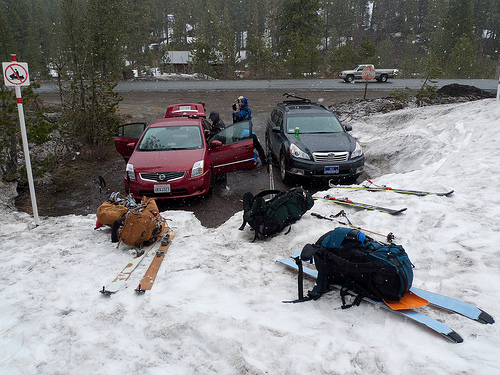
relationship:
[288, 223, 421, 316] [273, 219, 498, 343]
bag on top of skis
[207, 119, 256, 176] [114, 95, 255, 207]
door on vehicle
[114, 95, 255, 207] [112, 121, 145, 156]
vehicle has door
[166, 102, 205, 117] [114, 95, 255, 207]
trunk on car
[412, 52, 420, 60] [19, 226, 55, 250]
snow on ground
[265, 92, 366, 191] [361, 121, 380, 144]
vehicle by snow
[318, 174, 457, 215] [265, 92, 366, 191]
skis near car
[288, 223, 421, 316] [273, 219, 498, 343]
backpack on skis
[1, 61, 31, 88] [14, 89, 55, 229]
sign on pole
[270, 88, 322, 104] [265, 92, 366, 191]
rack on car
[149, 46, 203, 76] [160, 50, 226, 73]
cabin in picture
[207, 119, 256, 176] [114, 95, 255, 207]
door on car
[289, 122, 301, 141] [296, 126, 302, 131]
bottle has top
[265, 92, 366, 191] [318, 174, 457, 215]
car near ski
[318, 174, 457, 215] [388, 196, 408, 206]
ski on snow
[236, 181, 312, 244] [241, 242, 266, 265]
backpack on snow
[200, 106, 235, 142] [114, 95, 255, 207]
people in car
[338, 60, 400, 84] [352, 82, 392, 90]
car on road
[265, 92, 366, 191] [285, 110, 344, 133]
car has windshield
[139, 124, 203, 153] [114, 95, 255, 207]
windshield on car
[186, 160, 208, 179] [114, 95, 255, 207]
headlight on car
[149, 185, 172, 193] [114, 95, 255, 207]
plate on car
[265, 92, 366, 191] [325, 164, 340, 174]
car has plate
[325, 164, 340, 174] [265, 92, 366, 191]
plate on car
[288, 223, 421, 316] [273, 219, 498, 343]
bag on skis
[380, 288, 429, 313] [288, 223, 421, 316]
shovel under bag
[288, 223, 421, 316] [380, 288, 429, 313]
bag on shovel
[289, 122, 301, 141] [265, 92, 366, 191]
bottle on car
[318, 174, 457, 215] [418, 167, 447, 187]
ski in snow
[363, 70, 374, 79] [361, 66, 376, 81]
stop on sign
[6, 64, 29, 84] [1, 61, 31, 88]
picture on sign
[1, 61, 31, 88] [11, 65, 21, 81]
sign has line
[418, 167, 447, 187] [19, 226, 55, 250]
snow on ground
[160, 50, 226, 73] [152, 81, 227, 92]
house across street